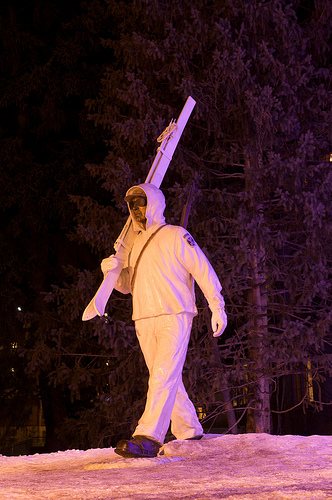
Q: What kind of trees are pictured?
A: Pine trees.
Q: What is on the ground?
A: Snow.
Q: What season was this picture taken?
A: Winter.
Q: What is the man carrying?
A: Skis.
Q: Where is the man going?
A: To ski.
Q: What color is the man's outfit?
A: White.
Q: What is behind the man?
A: Trees.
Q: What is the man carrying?
A: Skis.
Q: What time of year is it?
A: Winter.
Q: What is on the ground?
A: Snow.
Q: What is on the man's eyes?
A: Goggles.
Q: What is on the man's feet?
A: Boots.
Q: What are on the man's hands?
A: Mittens.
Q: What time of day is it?
A: Evening.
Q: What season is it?
A: Winter.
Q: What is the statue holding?
A: Skis.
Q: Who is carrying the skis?
A: A man.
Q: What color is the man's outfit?
A: White.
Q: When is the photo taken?
A: At night.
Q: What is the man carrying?
A: Skis and poles.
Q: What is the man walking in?
A: Snow.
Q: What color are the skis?
A: White.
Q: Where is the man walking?
A: On a ski hill.